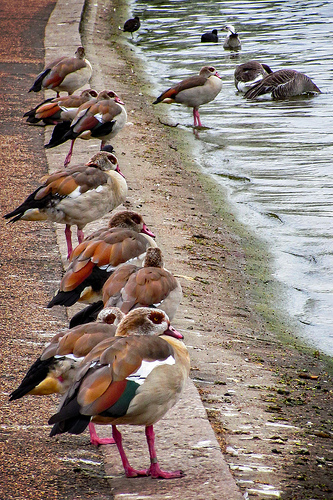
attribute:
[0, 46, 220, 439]
bird — in the picture, pink, leg, white, lake, feet, red, beek, standing, multicolored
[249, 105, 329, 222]
water — edge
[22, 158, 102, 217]
feather — multicolored, colored, brown, black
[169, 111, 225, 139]
leg — red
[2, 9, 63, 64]
walk way — covered